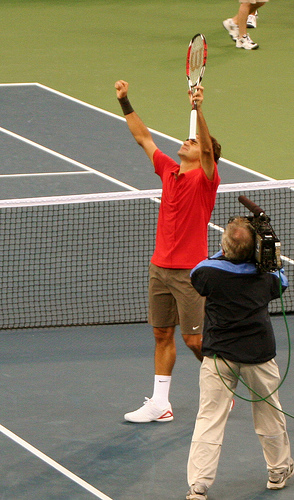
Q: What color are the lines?
A: White.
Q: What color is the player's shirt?
A: Red.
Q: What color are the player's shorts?
A: Brown.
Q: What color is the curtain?
A: Black.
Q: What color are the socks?
A: White.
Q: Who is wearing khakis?
A: The cameraman.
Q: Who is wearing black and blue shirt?
A: The cameraman.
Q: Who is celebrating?
A: Player.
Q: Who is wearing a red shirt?
A: The tennis player.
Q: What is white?
A: Shoes.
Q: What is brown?
A: Shorts.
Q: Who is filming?
A: Cameraman.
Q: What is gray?
A: Court.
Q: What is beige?
A: Pants.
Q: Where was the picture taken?
A: On a tennis court.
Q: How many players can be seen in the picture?
A: 1.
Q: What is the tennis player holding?
A: A racket.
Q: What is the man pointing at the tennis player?
A: A camera.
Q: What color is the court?
A: Blue and green.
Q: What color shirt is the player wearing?
A: Red.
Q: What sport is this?
A: Tennis.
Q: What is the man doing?
A: Celebrating.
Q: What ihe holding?
A: A racket.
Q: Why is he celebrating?
A: Victory.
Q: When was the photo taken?
A: After the match.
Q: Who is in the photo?
A: A man.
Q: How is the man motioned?
A: Arms raised.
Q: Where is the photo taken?
A: Tennis court.